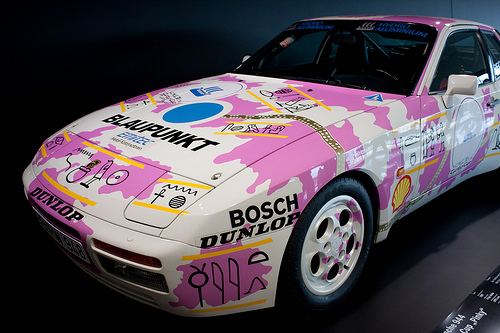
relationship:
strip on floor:
[423, 282, 480, 327] [315, 180, 496, 329]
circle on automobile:
[160, 97, 226, 124] [22, 14, 500, 317]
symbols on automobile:
[31, 92, 283, 227] [22, 14, 500, 317]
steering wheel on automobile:
[357, 60, 404, 91] [22, 14, 500, 317]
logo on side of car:
[384, 170, 426, 214] [59, 36, 481, 273]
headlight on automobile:
[92, 253, 179, 293] [17, 10, 499, 318]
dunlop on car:
[24, 185, 87, 228] [95, 57, 470, 278]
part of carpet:
[396, 290, 407, 309] [400, 222, 459, 282]